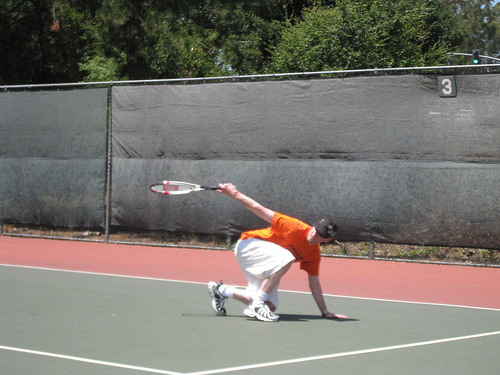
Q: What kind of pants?
A: Shorts.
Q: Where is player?
A: Tennis court.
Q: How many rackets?
A: One.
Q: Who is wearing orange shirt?
A: Player.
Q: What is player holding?
A: Tennis racket.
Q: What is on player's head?
A: Hat.